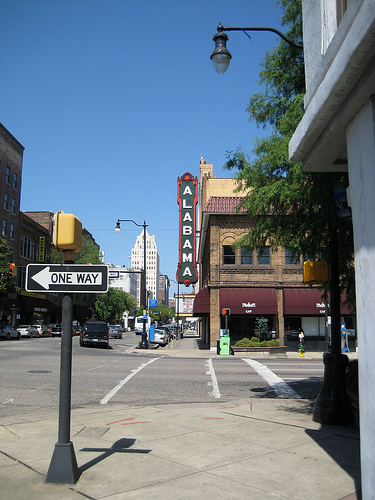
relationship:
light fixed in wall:
[211, 23, 234, 68] [279, 0, 373, 497]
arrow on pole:
[30, 266, 102, 291] [45, 299, 81, 482]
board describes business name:
[175, 172, 202, 287] [179, 180, 193, 281]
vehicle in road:
[140, 330, 171, 350] [0, 316, 351, 414]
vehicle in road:
[10, 320, 39, 345] [0, 316, 351, 414]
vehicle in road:
[29, 325, 51, 337] [0, 316, 351, 414]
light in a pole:
[211, 23, 234, 68] [227, 24, 361, 422]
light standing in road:
[211, 23, 234, 68] [0, 316, 358, 500]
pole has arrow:
[45, 299, 81, 482] [30, 266, 102, 291]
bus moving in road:
[133, 311, 156, 336] [0, 316, 351, 414]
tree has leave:
[228, 4, 370, 269] [233, 0, 357, 267]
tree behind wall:
[228, 4, 370, 269] [279, 0, 373, 497]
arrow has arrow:
[30, 266, 102, 291] [29, 266, 104, 289]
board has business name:
[175, 172, 202, 287] [179, 180, 193, 281]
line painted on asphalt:
[200, 353, 225, 404] [12, 325, 345, 424]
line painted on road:
[244, 358, 297, 397] [0, 316, 351, 414]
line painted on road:
[104, 353, 162, 402] [0, 316, 351, 414]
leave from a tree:
[233, 0, 357, 267] [228, 4, 370, 269]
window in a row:
[222, 242, 239, 267] [218, 242, 327, 272]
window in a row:
[240, 246, 257, 268] [218, 242, 327, 272]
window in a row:
[255, 248, 273, 267] [218, 242, 327, 272]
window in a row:
[286, 244, 302, 267] [218, 242, 327, 272]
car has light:
[78, 316, 112, 348] [74, 328, 84, 344]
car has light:
[78, 316, 112, 348] [104, 331, 111, 345]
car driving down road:
[78, 316, 112, 348] [0, 316, 351, 414]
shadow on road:
[259, 375, 365, 490] [0, 316, 358, 500]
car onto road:
[78, 316, 112, 348] [0, 316, 351, 414]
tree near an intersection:
[228, 4, 370, 269] [37, 342, 200, 405]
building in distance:
[133, 227, 172, 320] [96, 222, 179, 328]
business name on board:
[179, 180, 193, 281] [175, 172, 202, 287]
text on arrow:
[49, 271, 101, 290] [30, 266, 102, 291]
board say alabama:
[175, 172, 202, 287] [179, 180, 193, 281]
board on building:
[175, 172, 202, 287] [194, 161, 370, 348]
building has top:
[133, 227, 172, 320] [132, 224, 157, 240]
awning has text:
[192, 289, 353, 319] [239, 295, 259, 319]